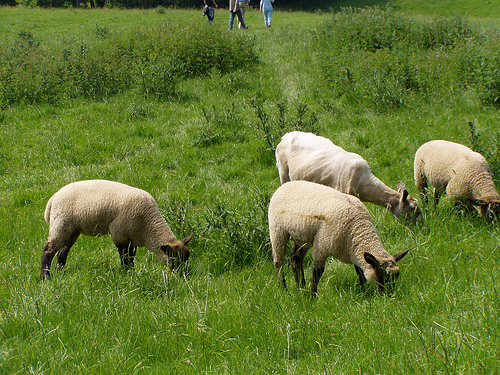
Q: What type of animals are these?
A: Sheep.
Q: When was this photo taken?
A: During the day.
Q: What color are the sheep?
A: White.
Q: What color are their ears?
A: Brown.